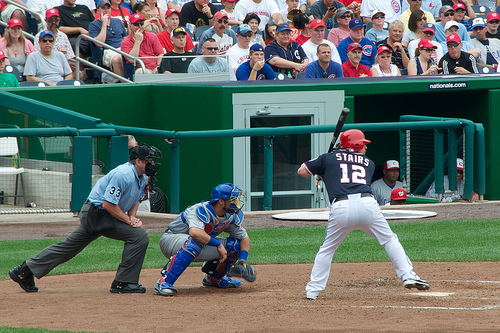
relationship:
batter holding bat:
[296, 126, 431, 303] [314, 105, 352, 191]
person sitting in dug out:
[371, 159, 408, 209] [353, 88, 491, 206]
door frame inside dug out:
[227, 89, 348, 212] [353, 88, 491, 206]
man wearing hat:
[437, 31, 475, 76] [444, 30, 462, 47]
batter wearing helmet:
[296, 126, 431, 303] [339, 129, 373, 153]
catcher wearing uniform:
[154, 181, 258, 297] [157, 199, 248, 295]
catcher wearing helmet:
[154, 181, 258, 297] [207, 182, 233, 208]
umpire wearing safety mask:
[8, 143, 164, 295] [144, 144, 163, 178]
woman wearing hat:
[406, 39, 444, 78] [415, 37, 436, 50]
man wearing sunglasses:
[437, 31, 475, 76] [445, 39, 463, 49]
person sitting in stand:
[371, 159, 408, 209] [2, 1, 499, 90]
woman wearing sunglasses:
[406, 39, 444, 78] [418, 46, 437, 55]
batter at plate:
[296, 126, 431, 303] [399, 288, 458, 302]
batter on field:
[296, 126, 431, 303] [1, 200, 500, 333]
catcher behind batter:
[154, 181, 258, 297] [296, 126, 431, 303]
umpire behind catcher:
[8, 143, 164, 295] [154, 181, 258, 297]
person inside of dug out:
[371, 159, 408, 209] [353, 88, 491, 206]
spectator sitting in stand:
[304, 41, 345, 82] [2, 1, 499, 90]